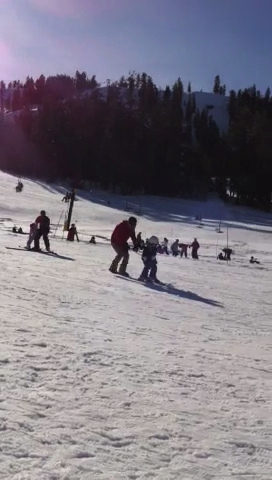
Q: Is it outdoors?
A: Yes, it is outdoors.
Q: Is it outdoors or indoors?
A: It is outdoors.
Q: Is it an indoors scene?
A: No, it is outdoors.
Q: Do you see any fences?
A: No, there are no fences.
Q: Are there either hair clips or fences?
A: No, there are no fences or hair clips.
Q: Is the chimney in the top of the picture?
A: Yes, the chimney is in the top of the image.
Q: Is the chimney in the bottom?
A: No, the chimney is in the top of the image.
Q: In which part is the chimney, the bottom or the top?
A: The chimney is in the top of the image.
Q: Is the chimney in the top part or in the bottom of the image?
A: The chimney is in the top of the image.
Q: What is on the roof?
A: The chimney is on the roof.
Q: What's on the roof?
A: The chimney is on the roof.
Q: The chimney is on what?
A: The chimney is on the roof.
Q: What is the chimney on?
A: The chimney is on the roof.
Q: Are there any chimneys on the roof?
A: Yes, there is a chimney on the roof.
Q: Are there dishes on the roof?
A: No, there is a chimney on the roof.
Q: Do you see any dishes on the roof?
A: No, there is a chimney on the roof.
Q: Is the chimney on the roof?
A: Yes, the chimney is on the roof.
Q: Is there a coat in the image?
A: Yes, there is a coat.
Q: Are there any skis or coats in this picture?
A: Yes, there is a coat.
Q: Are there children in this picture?
A: Yes, there is a child.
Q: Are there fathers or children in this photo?
A: Yes, there is a child.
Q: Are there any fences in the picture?
A: No, there are no fences.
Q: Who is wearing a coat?
A: The child is wearing a coat.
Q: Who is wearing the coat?
A: The child is wearing a coat.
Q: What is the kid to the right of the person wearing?
A: The kid is wearing a coat.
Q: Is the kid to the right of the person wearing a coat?
A: Yes, the child is wearing a coat.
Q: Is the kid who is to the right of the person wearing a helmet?
A: No, the kid is wearing a coat.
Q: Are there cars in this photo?
A: No, there are no cars.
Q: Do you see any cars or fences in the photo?
A: No, there are no cars or fences.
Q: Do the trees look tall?
A: Yes, the trees are tall.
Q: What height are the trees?
A: The trees are tall.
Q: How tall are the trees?
A: The trees are tall.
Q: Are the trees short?
A: No, the trees are tall.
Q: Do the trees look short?
A: No, the trees are tall.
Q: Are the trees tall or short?
A: The trees are tall.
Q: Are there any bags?
A: No, there are no bags.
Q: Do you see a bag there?
A: No, there are no bags.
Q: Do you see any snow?
A: Yes, there is snow.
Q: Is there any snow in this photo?
A: Yes, there is snow.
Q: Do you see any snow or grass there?
A: Yes, there is snow.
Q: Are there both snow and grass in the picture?
A: No, there is snow but no grass.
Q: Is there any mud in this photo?
A: No, there is no mud.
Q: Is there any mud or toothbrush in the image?
A: No, there are no mud or toothbrushes.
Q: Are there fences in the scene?
A: No, there are no fences.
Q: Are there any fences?
A: No, there are no fences.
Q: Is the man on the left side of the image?
A: Yes, the man is on the left of the image.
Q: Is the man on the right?
A: No, the man is on the left of the image.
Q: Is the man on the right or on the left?
A: The man is on the left of the image.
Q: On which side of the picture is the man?
A: The man is on the left of the image.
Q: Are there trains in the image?
A: No, there are no trains.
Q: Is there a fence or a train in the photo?
A: No, there are no trains or fences.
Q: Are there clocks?
A: No, there are no clocks.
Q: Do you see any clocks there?
A: No, there are no clocks.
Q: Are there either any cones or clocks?
A: No, there are no clocks or cones.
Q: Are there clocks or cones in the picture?
A: No, there are no clocks or cones.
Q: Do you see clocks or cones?
A: No, there are no clocks or cones.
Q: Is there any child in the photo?
A: Yes, there is a child.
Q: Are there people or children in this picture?
A: Yes, there is a child.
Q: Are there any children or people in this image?
A: Yes, there is a child.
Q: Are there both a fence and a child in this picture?
A: No, there is a child but no fences.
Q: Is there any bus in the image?
A: No, there are no buses.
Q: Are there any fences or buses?
A: No, there are no buses or fences.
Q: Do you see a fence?
A: No, there are no fences.